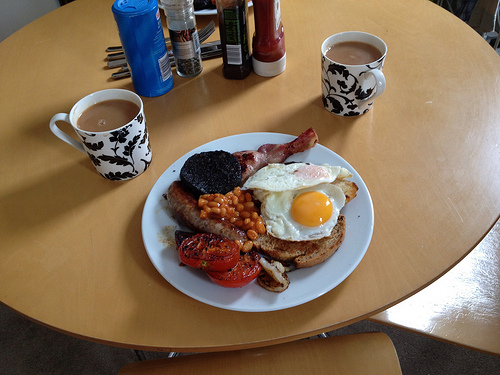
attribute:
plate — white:
[139, 129, 375, 312]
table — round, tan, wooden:
[0, 3, 498, 374]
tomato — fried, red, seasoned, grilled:
[178, 234, 240, 270]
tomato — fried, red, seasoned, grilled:
[209, 253, 260, 285]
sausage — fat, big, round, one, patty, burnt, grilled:
[178, 130, 319, 196]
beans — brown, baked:
[195, 186, 265, 240]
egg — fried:
[260, 183, 351, 240]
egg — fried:
[239, 157, 341, 194]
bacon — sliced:
[260, 123, 318, 160]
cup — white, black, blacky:
[50, 86, 152, 182]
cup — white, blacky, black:
[318, 29, 386, 118]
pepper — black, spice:
[164, 0, 201, 80]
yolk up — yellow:
[294, 192, 332, 227]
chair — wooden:
[118, 333, 402, 374]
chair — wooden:
[363, 214, 499, 354]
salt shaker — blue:
[113, 1, 176, 101]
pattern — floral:
[321, 64, 366, 118]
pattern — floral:
[84, 121, 146, 179]